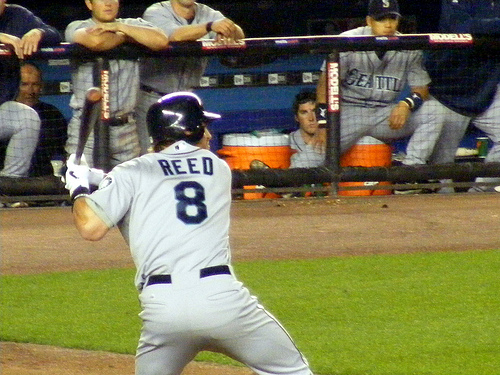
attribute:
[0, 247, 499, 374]
grass — green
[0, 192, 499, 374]
field — green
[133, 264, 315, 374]
pants — grey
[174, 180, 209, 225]
number — 8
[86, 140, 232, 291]
jersey — grey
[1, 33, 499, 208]
fence — metal, mesh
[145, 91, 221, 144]
helmet — black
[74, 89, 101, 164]
bat — brown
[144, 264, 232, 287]
belt — black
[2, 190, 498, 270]
strip — dirt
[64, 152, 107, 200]
gloves — white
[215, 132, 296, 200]
cooler — orange, white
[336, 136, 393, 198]
cooler — orange, white